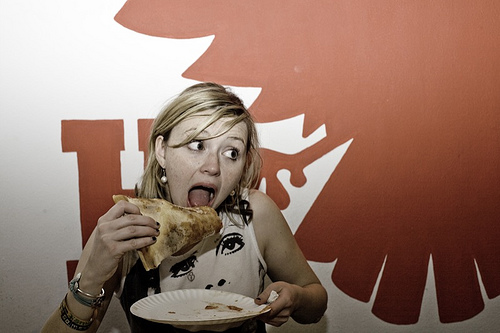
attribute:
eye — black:
[214, 232, 246, 257]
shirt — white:
[97, 181, 269, 330]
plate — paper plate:
[128, 291, 276, 326]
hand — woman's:
[257, 282, 294, 324]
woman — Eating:
[65, 76, 355, 328]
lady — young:
[40, 76, 327, 331]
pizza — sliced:
[111, 185, 224, 272]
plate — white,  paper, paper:
[127, 287, 277, 327]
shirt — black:
[107, 187, 287, 331]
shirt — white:
[140, 200, 238, 269]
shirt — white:
[118, 182, 270, 331]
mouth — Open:
[186, 182, 216, 207]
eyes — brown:
[178, 127, 250, 159]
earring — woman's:
[161, 164, 168, 187]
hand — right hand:
[85, 198, 160, 283]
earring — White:
[158, 168, 170, 183]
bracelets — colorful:
[51, 275, 104, 325]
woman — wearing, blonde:
[44, 80, 331, 332]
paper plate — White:
[128, 285, 270, 325]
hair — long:
[133, 81, 266, 205]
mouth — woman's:
[180, 181, 222, 208]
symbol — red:
[60, 1, 498, 325]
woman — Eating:
[30, 100, 343, 332]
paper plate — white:
[128, 286, 275, 330]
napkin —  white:
[264, 292, 275, 299]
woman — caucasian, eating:
[151, 85, 319, 331]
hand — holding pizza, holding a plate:
[256, 271, 302, 326]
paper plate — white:
[122, 283, 275, 324]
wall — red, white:
[2, 5, 472, 325]